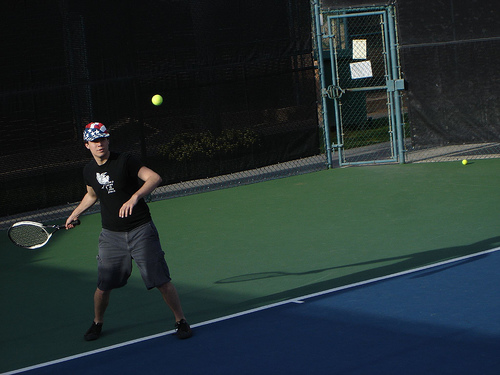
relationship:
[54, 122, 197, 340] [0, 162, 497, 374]
man standing on tennis court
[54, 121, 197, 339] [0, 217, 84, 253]
man holding racket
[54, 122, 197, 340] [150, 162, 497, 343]
man on tennis court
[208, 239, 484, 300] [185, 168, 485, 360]
shadow on court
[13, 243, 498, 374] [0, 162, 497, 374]
line painted on tennis court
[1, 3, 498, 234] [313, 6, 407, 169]
fence with door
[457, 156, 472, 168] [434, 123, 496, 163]
tennis ball lying against fence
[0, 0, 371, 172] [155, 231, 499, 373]
building behind court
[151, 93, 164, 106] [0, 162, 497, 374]
tennis ball on tennis court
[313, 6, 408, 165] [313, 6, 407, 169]
door in door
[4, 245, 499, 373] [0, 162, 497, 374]
inbounds on tennis court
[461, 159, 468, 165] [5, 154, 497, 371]
tennis ball on ground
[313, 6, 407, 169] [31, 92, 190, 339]
door behind man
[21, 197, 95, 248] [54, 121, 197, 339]
racket held by man